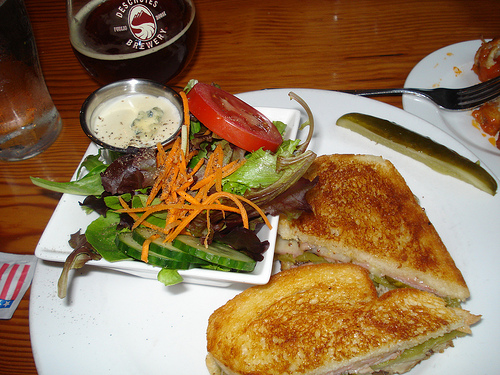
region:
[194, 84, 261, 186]
Large slice of tomato on salad.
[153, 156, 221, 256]
Thin slices of carrots on salad.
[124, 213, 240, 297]
Slices of cucumber on salad.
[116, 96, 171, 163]
White dressing in dressing container.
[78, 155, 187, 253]
Mixed greens in bottom of salad.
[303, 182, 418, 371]
Sandwich cut in half on plate.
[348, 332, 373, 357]
White bread toasted on sandwich.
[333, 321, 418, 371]
White colored meat on sandwich.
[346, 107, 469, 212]
Pickle spear on plate.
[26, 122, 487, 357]
Food on round white plate.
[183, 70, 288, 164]
A tomato slice.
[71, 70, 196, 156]
A bowl of dressing.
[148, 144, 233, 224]
The orange parts are carrots.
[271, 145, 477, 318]
A sandwich.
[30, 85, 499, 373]
The food is on a round white plate.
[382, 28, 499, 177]
A smaller plate is to the right.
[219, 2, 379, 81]
The table is made of wood.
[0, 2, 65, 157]
A glass is in the corner.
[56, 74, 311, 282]
A salad is on the plate.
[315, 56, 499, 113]
A fork is on the smaller plate.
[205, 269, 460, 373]
half of a sandwich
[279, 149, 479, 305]
half of a sandwich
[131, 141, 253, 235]
sliced carrot strips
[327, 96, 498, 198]
a slice of green pickle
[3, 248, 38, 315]
a red white and blue sugar packet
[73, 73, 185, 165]
a cup of dip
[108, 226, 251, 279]
three slices of cucumber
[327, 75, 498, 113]
a silver fork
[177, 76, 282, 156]
a slice of red tomato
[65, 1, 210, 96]
a glass of beer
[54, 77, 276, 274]
salad on a square plate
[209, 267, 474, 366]
half a grilled sandwich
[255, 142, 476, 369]
grilled sandwich with lettuce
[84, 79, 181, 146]
silver cup filled with salad dressing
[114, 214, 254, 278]
three cucumber slices on a plate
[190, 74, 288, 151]
thick slice of tomato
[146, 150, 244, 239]
shredded orange carrots with pepper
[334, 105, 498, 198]
slice of dill pickle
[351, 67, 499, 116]
used fork resting on a plate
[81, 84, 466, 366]
sandwich and salad for lunch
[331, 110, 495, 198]
Pickle spear on a white plate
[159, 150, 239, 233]
Carrot shavings on a salad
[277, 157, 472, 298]
Half of a sandwich on a plate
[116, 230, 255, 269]
Cucumber slices in a salad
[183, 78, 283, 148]
tomato slice in a salad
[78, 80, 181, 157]
white salad dressing in a metal dish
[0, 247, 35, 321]
Red white and blue flag on a package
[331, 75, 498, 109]
Fork on a plate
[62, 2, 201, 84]
Glass with a dark beer inside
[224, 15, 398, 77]
Wooden table with plates on it